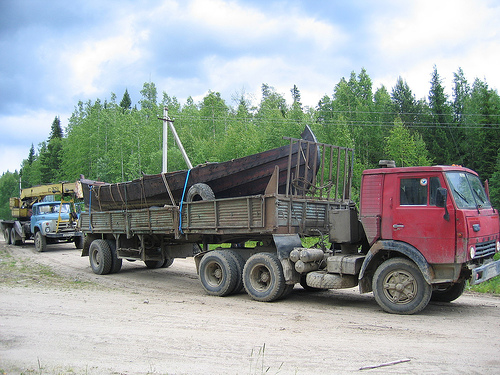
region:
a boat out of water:
[64, 101, 328, 233]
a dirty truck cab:
[299, 133, 499, 320]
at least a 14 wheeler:
[70, 96, 497, 309]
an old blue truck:
[4, 176, 90, 254]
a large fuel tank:
[319, 244, 368, 282]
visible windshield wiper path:
[441, 164, 494, 217]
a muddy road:
[0, 238, 212, 300]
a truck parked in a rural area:
[63, 146, 493, 326]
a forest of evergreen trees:
[16, 51, 493, 191]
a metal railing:
[272, 126, 366, 211]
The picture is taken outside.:
[3, 5, 472, 363]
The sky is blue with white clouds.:
[14, 13, 486, 103]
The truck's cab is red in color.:
[337, 119, 499, 319]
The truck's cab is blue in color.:
[28, 188, 79, 245]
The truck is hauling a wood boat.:
[83, 150, 339, 207]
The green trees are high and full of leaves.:
[39, 67, 497, 164]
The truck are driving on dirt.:
[8, 174, 498, 371]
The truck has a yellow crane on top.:
[17, 162, 88, 207]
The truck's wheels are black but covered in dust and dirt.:
[85, 231, 418, 319]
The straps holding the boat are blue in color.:
[82, 175, 233, 244]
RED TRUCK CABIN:
[352, 151, 497, 263]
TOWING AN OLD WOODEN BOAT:
[79, 128, 325, 229]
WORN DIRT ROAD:
[51, 259, 281, 343]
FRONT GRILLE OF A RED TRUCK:
[458, 233, 498, 278]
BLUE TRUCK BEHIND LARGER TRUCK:
[23, 183, 85, 258]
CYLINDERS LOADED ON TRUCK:
[279, 228, 328, 298]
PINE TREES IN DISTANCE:
[352, 114, 468, 176]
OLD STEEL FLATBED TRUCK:
[82, 185, 279, 248]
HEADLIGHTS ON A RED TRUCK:
[460, 230, 498, 268]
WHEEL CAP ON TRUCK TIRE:
[368, 246, 435, 321]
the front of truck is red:
[358, 168, 498, 245]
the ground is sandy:
[93, 298, 300, 358]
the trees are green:
[71, 124, 162, 155]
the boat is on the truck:
[82, 137, 314, 208]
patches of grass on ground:
[24, 261, 56, 281]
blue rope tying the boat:
[173, 165, 207, 210]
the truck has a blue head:
[29, 203, 73, 240]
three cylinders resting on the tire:
[285, 241, 325, 273]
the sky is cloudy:
[186, 26, 331, 66]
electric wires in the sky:
[147, 110, 315, 133]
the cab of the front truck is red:
[355, 162, 499, 269]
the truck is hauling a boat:
[79, 103, 311, 214]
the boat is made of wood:
[78, 120, 328, 217]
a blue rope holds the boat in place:
[174, 165, 191, 235]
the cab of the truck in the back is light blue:
[30, 199, 86, 241]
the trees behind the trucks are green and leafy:
[3, 67, 499, 294]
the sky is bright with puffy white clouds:
[0, 0, 499, 182]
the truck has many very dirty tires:
[85, 235, 469, 316]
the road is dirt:
[1, 230, 498, 373]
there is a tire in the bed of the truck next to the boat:
[185, 182, 220, 207]